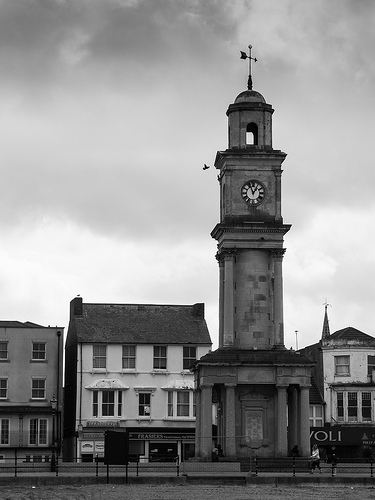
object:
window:
[153, 346, 167, 369]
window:
[92, 390, 99, 415]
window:
[183, 344, 196, 369]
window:
[336, 393, 344, 422]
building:
[296, 298, 375, 460]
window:
[0, 377, 7, 399]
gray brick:
[4, 481, 374, 499]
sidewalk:
[1, 470, 372, 496]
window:
[0, 419, 9, 446]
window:
[30, 376, 46, 400]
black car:
[148, 443, 177, 463]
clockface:
[242, 183, 264, 203]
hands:
[249, 183, 254, 194]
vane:
[239, 51, 258, 62]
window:
[117, 392, 122, 416]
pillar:
[273, 385, 288, 458]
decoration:
[322, 302, 330, 339]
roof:
[298, 326, 375, 351]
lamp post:
[50, 398, 58, 473]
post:
[291, 445, 300, 477]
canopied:
[192, 303, 204, 320]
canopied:
[69, 294, 82, 317]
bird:
[202, 163, 209, 170]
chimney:
[69, 297, 83, 319]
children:
[310, 444, 324, 474]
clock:
[241, 179, 267, 207]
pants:
[313, 458, 322, 471]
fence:
[0, 456, 374, 499]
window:
[93, 344, 107, 368]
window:
[102, 390, 114, 416]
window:
[167, 390, 197, 419]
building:
[65, 294, 213, 462]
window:
[31, 341, 47, 360]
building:
[0, 320, 65, 461]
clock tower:
[190, 46, 318, 472]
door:
[239, 392, 269, 447]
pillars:
[199, 384, 212, 463]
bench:
[239, 456, 311, 477]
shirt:
[311, 448, 321, 461]